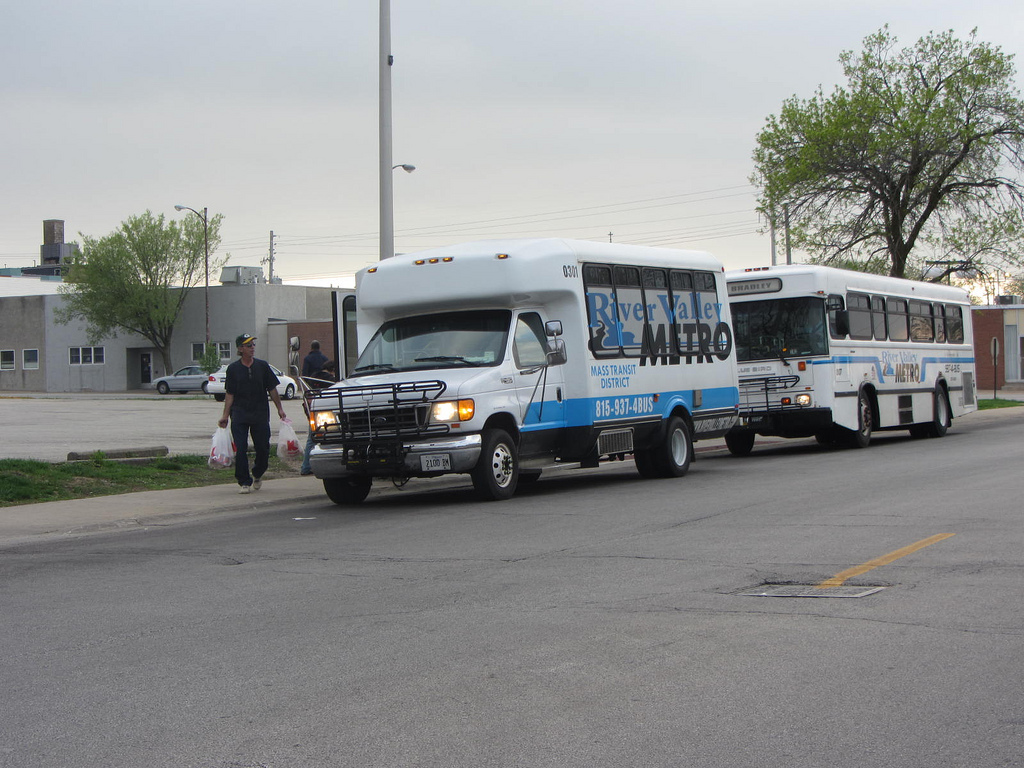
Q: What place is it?
A: It is a road.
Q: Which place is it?
A: It is a road.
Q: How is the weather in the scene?
A: It is overcast.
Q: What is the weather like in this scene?
A: It is overcast.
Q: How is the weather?
A: It is overcast.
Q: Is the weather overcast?
A: Yes, it is overcast.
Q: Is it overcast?
A: Yes, it is overcast.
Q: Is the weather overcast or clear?
A: It is overcast.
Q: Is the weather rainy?
A: No, it is overcast.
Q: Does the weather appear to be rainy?
A: No, it is overcast.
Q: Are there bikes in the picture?
A: No, there are no bikes.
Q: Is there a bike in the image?
A: No, there are no bikes.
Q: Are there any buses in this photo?
A: Yes, there are buses.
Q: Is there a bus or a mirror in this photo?
A: Yes, there are buses.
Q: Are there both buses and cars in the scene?
A: Yes, there are both buses and a car.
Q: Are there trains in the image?
A: No, there are no trains.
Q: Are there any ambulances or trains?
A: No, there are no trains or ambulances.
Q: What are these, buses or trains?
A: These are buses.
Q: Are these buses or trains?
A: These are buses.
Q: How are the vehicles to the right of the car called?
A: The vehicles are buses.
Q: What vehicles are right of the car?
A: The vehicles are buses.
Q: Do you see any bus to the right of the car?
A: Yes, there are buses to the right of the car.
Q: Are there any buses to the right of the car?
A: Yes, there are buses to the right of the car.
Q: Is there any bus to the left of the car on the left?
A: No, the buses are to the right of the car.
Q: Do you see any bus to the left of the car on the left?
A: No, the buses are to the right of the car.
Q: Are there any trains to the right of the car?
A: No, there are buses to the right of the car.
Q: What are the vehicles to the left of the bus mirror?
A: The vehicles are buses.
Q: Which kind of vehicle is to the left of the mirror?
A: The vehicles are buses.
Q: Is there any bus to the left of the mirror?
A: Yes, there are buses to the left of the mirror.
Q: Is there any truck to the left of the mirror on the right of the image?
A: No, there are buses to the left of the mirror.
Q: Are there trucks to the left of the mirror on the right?
A: No, there are buses to the left of the mirror.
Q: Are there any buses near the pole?
A: Yes, there are buses near the pole.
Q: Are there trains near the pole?
A: No, there are buses near the pole.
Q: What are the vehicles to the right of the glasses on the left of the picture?
A: The vehicles are buses.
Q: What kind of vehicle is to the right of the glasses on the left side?
A: The vehicles are buses.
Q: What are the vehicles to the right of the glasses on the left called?
A: The vehicles are buses.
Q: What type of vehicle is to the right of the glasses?
A: The vehicles are buses.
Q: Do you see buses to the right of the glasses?
A: Yes, there are buses to the right of the glasses.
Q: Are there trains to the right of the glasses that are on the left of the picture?
A: No, there are buses to the right of the glasses.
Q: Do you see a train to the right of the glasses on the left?
A: No, there are buses to the right of the glasses.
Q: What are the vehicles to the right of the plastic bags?
A: The vehicles are buses.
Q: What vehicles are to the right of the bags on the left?
A: The vehicles are buses.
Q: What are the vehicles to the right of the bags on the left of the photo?
A: The vehicles are buses.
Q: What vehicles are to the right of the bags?
A: The vehicles are buses.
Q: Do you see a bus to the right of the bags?
A: Yes, there are buses to the right of the bags.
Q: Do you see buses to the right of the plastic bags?
A: Yes, there are buses to the right of the bags.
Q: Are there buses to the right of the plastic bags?
A: Yes, there are buses to the right of the bags.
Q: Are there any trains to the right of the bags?
A: No, there are buses to the right of the bags.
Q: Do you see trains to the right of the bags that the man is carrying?
A: No, there are buses to the right of the bags.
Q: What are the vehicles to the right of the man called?
A: The vehicles are buses.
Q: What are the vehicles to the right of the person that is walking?
A: The vehicles are buses.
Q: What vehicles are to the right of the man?
A: The vehicles are buses.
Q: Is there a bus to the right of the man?
A: Yes, there are buses to the right of the man.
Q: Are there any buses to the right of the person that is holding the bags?
A: Yes, there are buses to the right of the man.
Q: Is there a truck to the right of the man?
A: No, there are buses to the right of the man.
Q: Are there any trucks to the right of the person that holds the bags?
A: No, there are buses to the right of the man.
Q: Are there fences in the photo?
A: No, there are no fences.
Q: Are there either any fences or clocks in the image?
A: No, there are no fences or clocks.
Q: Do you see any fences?
A: No, there are no fences.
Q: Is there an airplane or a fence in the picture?
A: No, there are no fences or airplanes.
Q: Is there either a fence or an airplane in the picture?
A: No, there are no fences or airplanes.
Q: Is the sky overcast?
A: Yes, the sky is overcast.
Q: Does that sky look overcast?
A: Yes, the sky is overcast.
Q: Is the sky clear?
A: No, the sky is overcast.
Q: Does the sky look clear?
A: No, the sky is overcast.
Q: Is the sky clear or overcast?
A: The sky is overcast.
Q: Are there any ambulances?
A: No, there are no ambulances.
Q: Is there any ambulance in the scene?
A: No, there are no ambulances.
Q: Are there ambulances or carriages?
A: No, there are no ambulances or carriages.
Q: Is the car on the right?
A: No, the car is on the left of the image.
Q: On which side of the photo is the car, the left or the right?
A: The car is on the left of the image.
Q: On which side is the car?
A: The car is on the left of the image.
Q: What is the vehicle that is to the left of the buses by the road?
A: The vehicle is a car.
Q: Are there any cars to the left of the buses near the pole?
A: Yes, there is a car to the left of the buses.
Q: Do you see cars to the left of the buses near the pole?
A: Yes, there is a car to the left of the buses.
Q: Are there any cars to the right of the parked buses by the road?
A: No, the car is to the left of the buses.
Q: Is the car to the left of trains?
A: No, the car is to the left of the buses.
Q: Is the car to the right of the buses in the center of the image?
A: No, the car is to the left of the buses.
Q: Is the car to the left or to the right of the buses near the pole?
A: The car is to the left of the buses.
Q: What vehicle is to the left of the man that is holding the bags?
A: The vehicle is a car.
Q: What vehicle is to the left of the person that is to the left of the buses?
A: The vehicle is a car.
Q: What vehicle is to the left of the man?
A: The vehicle is a car.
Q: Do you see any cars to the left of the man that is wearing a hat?
A: Yes, there is a car to the left of the man.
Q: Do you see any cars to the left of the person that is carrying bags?
A: Yes, there is a car to the left of the man.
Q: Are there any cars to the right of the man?
A: No, the car is to the left of the man.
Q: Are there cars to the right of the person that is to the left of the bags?
A: No, the car is to the left of the man.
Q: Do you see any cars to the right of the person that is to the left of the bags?
A: No, the car is to the left of the man.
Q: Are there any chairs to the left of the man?
A: No, there is a car to the left of the man.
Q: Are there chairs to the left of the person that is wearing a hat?
A: No, there is a car to the left of the man.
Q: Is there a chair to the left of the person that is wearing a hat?
A: No, there is a car to the left of the man.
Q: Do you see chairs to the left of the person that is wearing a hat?
A: No, there is a car to the left of the man.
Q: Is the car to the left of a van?
A: No, the car is to the left of the man.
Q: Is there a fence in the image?
A: No, there are no fences.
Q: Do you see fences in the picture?
A: No, there are no fences.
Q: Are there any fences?
A: No, there are no fences.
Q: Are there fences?
A: No, there are no fences.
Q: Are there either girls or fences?
A: No, there are no fences or girls.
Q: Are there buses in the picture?
A: Yes, there is a bus.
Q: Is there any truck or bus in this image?
A: Yes, there is a bus.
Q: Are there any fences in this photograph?
A: No, there are no fences.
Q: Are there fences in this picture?
A: No, there are no fences.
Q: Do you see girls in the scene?
A: No, there are no girls.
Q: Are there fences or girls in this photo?
A: No, there are no girls or fences.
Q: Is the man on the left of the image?
A: Yes, the man is on the left of the image.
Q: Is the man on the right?
A: No, the man is on the left of the image.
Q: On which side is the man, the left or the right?
A: The man is on the left of the image.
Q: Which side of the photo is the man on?
A: The man is on the left of the image.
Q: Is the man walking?
A: Yes, the man is walking.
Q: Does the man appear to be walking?
A: Yes, the man is walking.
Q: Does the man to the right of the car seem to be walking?
A: Yes, the man is walking.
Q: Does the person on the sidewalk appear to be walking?
A: Yes, the man is walking.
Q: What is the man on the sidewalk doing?
A: The man is walking.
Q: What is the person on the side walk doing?
A: The man is walking.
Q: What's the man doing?
A: The man is walking.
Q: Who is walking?
A: The man is walking.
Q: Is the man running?
A: No, the man is walking.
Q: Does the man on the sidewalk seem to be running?
A: No, the man is walking.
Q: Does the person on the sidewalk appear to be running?
A: No, the man is walking.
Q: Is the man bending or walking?
A: The man is walking.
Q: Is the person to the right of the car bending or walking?
A: The man is walking.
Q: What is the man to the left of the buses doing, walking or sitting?
A: The man is walking.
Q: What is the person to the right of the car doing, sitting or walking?
A: The man is walking.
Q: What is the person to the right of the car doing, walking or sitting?
A: The man is walking.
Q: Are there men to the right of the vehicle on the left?
A: Yes, there is a man to the right of the car.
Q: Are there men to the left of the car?
A: No, the man is to the right of the car.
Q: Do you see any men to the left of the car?
A: No, the man is to the right of the car.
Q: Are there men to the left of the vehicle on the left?
A: No, the man is to the right of the car.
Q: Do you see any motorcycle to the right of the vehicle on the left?
A: No, there is a man to the right of the car.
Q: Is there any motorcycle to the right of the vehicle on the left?
A: No, there is a man to the right of the car.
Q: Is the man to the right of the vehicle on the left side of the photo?
A: Yes, the man is to the right of the car.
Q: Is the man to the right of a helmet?
A: No, the man is to the right of the car.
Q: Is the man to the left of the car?
A: No, the man is to the right of the car.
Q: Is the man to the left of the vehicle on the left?
A: No, the man is to the right of the car.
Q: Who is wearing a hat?
A: The man is wearing a hat.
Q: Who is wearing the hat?
A: The man is wearing a hat.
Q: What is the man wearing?
A: The man is wearing a hat.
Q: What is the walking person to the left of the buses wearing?
A: The man is wearing a hat.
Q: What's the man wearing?
A: The man is wearing a hat.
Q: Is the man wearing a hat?
A: Yes, the man is wearing a hat.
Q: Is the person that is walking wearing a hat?
A: Yes, the man is wearing a hat.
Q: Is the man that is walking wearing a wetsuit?
A: No, the man is wearing a hat.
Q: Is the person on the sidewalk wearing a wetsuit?
A: No, the man is wearing a hat.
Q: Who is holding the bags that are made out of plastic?
A: The man is holding the bags.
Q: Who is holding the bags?
A: The man is holding the bags.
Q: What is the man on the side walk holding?
A: The man is holding the bags.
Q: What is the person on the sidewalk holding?
A: The man is holding the bags.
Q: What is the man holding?
A: The man is holding the bags.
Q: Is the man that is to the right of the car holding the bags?
A: Yes, the man is holding the bags.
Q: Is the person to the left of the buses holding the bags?
A: Yes, the man is holding the bags.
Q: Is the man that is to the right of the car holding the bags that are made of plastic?
A: Yes, the man is holding the bags.